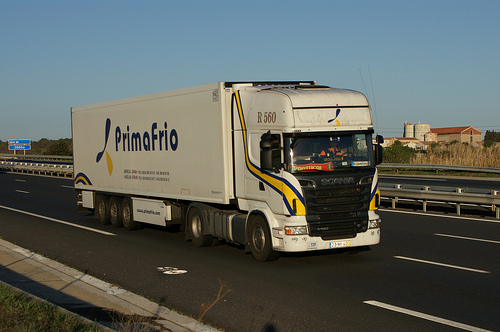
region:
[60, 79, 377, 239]
this is a transist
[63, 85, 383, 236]
the trailer is white in color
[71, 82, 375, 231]
the trailer is long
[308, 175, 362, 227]
the front is black in color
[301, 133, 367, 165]
this is the front screen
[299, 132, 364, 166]
the front screen is clear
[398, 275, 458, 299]
the road is tarmacked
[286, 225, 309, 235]
the light is off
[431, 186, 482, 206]
the fence is short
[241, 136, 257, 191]
the door is closed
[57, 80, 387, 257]
PrimaFrio truck speeds highway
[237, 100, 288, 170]
Truck identification number R 560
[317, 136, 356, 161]
Driver orange jacket at wheel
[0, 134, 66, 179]
Blue highway sign directions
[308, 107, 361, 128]
Company logo truck cab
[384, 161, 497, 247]
Median guardrails protect highway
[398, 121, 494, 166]
Farm buildings silo attached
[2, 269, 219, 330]
Cement breakdown lane bottom left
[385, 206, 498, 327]
White painted lines separate lanes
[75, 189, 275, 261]
Five tires shown bottom truck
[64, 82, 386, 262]
a semi truck going down the freeway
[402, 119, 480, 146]
some buildings off to the side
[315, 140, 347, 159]
the person driving the truck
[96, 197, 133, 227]
the wheels on the back of the truck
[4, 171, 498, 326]
the road the truck is driving on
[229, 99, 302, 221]
the blue and yellow stripe on the side of the cab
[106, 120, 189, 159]
the name of the company that owns the truck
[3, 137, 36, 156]
the freeway sign on the side of the road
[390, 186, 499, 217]
the metal divider in the center of the road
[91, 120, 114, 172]
the logo on the side of the truck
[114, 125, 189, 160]
the word PrimaFrio on the side of a truck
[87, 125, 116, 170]
a blue and yellow symbol on the side of a truck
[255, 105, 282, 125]
R 560 on the side of the front of the truck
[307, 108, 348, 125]
a blue and yellow symbol on the front of a truck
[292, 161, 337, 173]
a red tag with white letters in the front windshield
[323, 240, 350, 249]
a license plate on the front of a truck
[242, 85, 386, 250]
the front end of a truck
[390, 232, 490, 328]
three white lines on the road in front of a truck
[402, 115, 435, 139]
Three silos behind a building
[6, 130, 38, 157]
a blue sign with white lettering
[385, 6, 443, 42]
part of the sky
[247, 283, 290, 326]
part of a road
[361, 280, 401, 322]
part of a white line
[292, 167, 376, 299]
front of a truck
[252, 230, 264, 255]
part of a rim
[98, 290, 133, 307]
edge of a road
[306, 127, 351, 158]
part of a window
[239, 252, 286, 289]
part of a road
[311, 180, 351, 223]
part of a truck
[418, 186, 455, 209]
part of a boundary